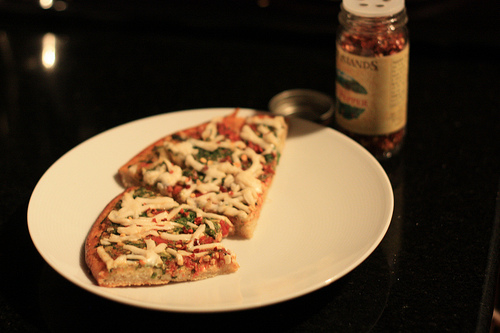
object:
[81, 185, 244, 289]
of pizza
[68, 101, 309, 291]
pizza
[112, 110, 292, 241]
one pizza slice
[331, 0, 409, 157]
container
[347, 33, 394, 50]
condiment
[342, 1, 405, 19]
covering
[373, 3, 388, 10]
round holes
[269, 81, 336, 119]
lid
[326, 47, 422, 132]
label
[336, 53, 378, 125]
writing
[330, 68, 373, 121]
semicircles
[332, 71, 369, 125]
front of bottle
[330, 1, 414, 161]
bottle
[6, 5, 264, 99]
table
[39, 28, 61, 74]
reflection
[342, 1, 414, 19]
cover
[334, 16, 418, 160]
spice container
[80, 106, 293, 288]
two pizza pieces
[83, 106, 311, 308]
middle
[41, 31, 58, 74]
light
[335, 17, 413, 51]
plastic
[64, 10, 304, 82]
black surface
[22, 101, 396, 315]
one plate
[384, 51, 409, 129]
label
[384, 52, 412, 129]
side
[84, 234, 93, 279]
outer edge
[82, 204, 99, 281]
crust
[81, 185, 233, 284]
pizza piece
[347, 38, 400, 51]
peppers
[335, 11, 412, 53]
jar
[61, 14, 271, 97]
tabletop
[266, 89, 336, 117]
cover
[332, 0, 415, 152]
spice jar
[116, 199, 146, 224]
cheese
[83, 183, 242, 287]
top of pizza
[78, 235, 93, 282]
bottom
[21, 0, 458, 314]
meal